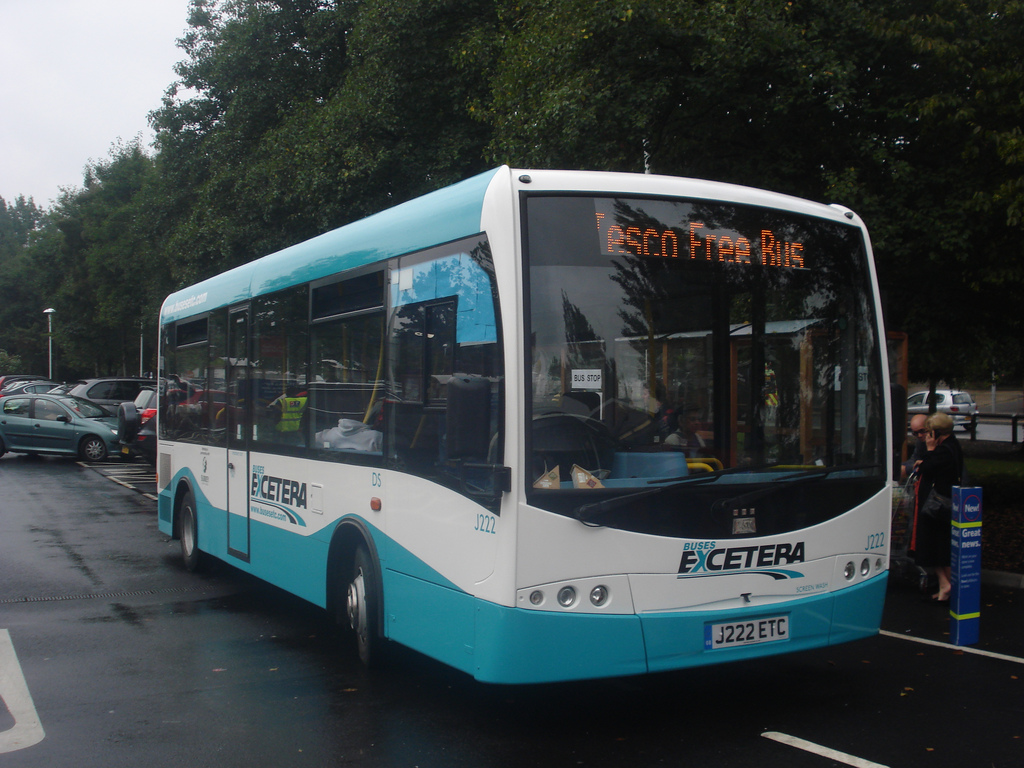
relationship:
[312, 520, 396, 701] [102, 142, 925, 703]
front tire on bus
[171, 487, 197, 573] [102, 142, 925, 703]
tire on bus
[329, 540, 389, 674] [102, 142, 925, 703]
front tire on bus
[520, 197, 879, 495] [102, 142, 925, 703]
windshield on bus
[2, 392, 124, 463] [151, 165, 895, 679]
car behind bus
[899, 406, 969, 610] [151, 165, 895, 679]
people on front of bus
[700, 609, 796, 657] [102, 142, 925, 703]
plate on front of bus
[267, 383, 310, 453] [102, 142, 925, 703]
person on bus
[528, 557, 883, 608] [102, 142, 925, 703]
bus lights on bus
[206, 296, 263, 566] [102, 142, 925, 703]
door of bus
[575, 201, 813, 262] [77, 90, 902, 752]
letters on top of bus